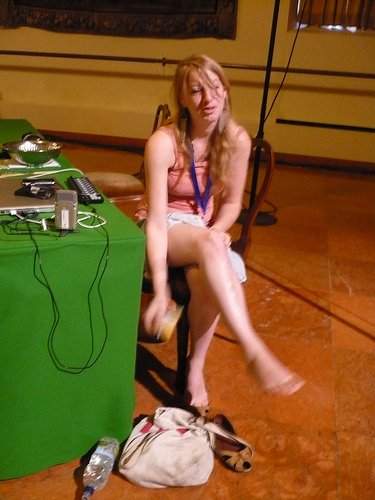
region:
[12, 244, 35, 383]
Green table with items on it.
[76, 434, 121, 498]
Water bottle on the floor.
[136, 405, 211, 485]
Purse on the floor.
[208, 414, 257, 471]
Shoe sitting on the floor.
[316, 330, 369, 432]
Tile flooring in a room.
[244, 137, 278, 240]
Chair the girl is sitting on.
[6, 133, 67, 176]
Silver bowl on the table.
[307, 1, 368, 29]
Curtain in the window.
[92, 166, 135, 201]
Chair next to the girl.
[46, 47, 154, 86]
Bar against the wall.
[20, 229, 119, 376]
This is a cable.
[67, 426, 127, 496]
This is a water bottle.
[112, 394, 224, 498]
This is a bag.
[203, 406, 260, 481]
This is a shoe.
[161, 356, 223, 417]
This is a left foot.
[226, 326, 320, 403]
This is the right foot.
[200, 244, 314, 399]
This is a leg.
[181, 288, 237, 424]
This is the left leg.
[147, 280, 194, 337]
This is a hand.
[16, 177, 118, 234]
These are electronics on a table.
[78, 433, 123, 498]
Water bottle shown on the ground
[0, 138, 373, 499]
Brown tile floor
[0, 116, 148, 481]
Fitted green table cloth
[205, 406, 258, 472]
On of the shoes of the person shown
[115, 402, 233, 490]
White cloth bag shown on the ground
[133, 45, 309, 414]
Blonde woman shown in the photo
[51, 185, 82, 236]
Silver speaker on the table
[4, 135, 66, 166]
Silver bowl lying on the table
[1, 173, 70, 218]
Silver laptop resting on the table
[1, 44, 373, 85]
Rail that runs along the back wall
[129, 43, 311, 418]
A woman is sitting.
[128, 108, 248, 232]
A woman is wearing a pink top.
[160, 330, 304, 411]
A woman is barefoot.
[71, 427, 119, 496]
A water bottle is on the floor.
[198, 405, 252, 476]
A shoe is on the floor.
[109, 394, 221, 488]
A bag is on the floor.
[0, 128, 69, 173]
A bowl is on the table.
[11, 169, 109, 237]
Devices are on the table.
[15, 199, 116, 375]
A cable is hanging from the table.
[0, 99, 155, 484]
A table is covered in green material.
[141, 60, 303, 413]
the woman is sitting down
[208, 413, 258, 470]
a shoe is on the floor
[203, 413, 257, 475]
the shoe is brown in color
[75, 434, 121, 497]
a water bottle is on the floor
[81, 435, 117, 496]
the water bottle is transparent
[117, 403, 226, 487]
a white bag is on the floor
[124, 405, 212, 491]
the bag is white in color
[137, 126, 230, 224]
the woman is wearing a tank top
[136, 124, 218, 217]
the tank top is peach in color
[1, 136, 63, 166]
a metal bowl is on the table